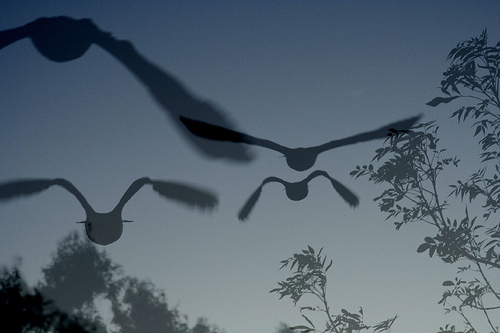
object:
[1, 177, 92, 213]
wing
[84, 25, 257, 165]
wing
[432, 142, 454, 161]
ground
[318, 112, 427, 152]
wing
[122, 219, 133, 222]
line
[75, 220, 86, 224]
line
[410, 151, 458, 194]
ground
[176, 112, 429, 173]
drone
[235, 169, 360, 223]
drone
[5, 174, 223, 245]
drone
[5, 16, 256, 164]
drone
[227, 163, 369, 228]
green grass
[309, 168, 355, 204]
wing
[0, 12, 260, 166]
shadow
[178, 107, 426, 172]
shadow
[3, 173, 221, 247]
shadow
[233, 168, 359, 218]
shadow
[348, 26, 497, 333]
leaves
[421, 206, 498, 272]
branch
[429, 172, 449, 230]
stems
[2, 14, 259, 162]
bird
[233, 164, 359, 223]
bird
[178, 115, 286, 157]
wing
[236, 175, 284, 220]
wing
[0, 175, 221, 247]
something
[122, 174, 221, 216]
wing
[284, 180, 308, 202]
body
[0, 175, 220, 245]
bird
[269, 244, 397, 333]
branch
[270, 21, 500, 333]
plants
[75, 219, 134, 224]
stick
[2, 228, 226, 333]
tree line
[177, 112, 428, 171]
bird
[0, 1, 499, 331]
sky